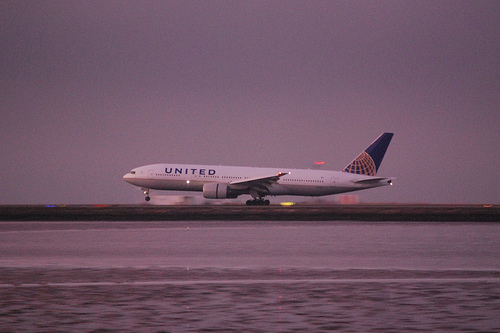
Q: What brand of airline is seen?
A: United.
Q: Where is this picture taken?
A: The ocean.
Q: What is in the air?
A: A plane.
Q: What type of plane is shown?
A: Commercial.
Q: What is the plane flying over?
A: Water.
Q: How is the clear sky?
A: Cloudless.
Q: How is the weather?
A: Overcast.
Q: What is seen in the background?
A: The land.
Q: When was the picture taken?
A: Early evening.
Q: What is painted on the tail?
A: United logo.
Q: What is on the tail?
A: Globe.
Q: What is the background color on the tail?
A: Globe.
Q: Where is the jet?
A: Over the runway.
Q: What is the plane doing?
A: Landing.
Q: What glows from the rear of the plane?
A: Tail lights.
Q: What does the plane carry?
A: Passengers.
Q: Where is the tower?
A: Behind the plane.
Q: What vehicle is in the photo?
A: Airplane.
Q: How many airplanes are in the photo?
A: One.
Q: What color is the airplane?
A: White and blue.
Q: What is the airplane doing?
A: Flying.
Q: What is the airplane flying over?
A: Body of water.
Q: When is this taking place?
A: Evening.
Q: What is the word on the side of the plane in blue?
A: United.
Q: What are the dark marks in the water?
A: Ripples.